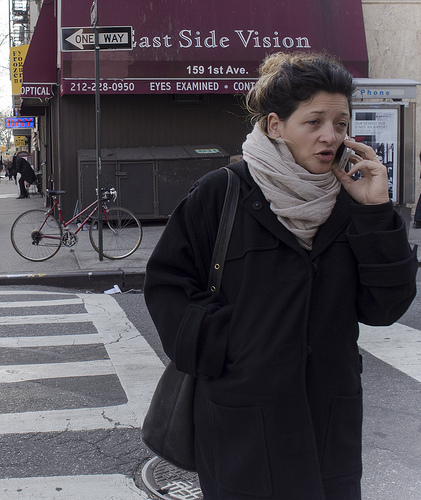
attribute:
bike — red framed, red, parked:
[11, 185, 143, 261]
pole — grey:
[93, 21, 100, 262]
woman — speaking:
[141, 52, 413, 499]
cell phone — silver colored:
[337, 142, 350, 172]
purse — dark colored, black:
[141, 167, 241, 474]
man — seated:
[6, 156, 32, 197]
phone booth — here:
[352, 77, 420, 208]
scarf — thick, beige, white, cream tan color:
[242, 122, 351, 249]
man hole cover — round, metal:
[145, 453, 203, 499]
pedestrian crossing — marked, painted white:
[1, 287, 182, 499]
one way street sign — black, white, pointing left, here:
[60, 26, 132, 53]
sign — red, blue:
[3, 113, 35, 131]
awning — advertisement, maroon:
[59, 3, 368, 94]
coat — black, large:
[145, 157, 414, 499]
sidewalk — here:
[0, 168, 166, 275]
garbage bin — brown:
[77, 143, 232, 222]